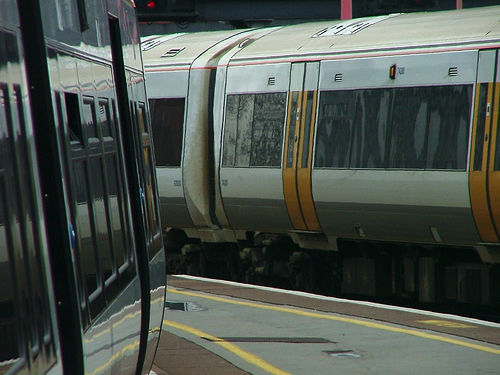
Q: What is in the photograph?
A: A subway.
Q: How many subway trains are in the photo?
A: Two.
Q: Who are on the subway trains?
A: People.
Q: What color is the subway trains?
A: Gray.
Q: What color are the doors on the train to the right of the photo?
A: Yellow.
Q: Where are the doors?
A: The side of the train.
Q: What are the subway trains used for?
A: Transportation.